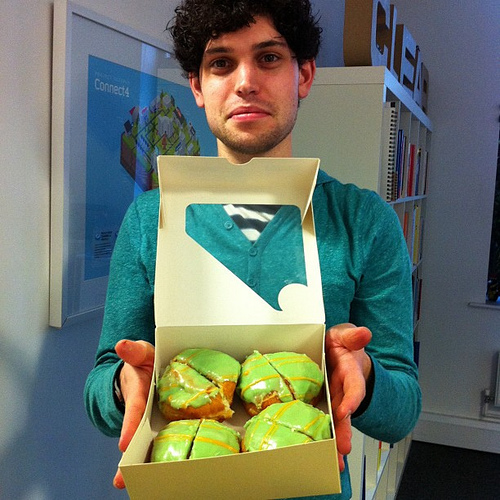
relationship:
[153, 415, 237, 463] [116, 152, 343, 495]
donunt in box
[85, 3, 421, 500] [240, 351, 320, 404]
man displaying donunt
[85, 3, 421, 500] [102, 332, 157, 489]
man has hand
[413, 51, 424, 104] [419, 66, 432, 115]
letter next to letter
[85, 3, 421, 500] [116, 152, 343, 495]
man holding box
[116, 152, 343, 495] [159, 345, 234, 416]
box has donunt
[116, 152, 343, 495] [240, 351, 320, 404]
box has donunt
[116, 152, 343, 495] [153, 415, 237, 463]
box has donunt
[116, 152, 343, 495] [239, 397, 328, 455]
box has donunt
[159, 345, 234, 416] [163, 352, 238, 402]
donunt has frosting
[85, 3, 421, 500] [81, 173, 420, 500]
man wearing henley shirt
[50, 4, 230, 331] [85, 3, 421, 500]
picture frame behind man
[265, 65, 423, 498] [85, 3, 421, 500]
bookshelf behind man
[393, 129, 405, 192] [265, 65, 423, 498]
book on bookshelf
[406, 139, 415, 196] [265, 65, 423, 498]
book on bookshelf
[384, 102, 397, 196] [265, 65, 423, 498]
book on bookshelf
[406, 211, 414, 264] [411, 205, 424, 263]
book next to book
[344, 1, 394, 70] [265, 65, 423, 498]
letter on top of bookshelf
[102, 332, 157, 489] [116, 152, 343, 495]
hand holding box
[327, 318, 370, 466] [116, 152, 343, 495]
hand holding box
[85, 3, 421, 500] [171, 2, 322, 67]
man has hair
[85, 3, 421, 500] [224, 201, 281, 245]
man wears shirt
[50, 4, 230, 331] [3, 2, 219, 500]
picture frame hanging on wall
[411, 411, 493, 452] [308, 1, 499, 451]
moulding at base of wall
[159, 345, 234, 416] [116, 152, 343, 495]
donunt in box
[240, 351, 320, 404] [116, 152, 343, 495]
donunt in box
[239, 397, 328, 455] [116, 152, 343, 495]
donunt in box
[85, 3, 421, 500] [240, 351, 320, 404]
man holding donunt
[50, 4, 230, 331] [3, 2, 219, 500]
picture frame on wall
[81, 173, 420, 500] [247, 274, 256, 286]
henley shirt has button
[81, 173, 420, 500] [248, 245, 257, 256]
henley shirt has button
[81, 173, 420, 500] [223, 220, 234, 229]
henley shirt has button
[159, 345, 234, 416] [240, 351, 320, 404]
donunt next to donunt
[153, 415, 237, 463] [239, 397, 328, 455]
donunt next to donunt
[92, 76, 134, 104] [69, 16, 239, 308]
connect4 word on picture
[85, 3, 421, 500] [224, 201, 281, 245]
man wearing shirt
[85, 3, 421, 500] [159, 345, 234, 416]
man holding donunt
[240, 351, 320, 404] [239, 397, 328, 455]
donunt next to donunt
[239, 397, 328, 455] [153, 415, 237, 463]
donunt next to donunt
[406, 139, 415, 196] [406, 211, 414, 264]
book next to book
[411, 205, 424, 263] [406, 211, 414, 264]
book next to book